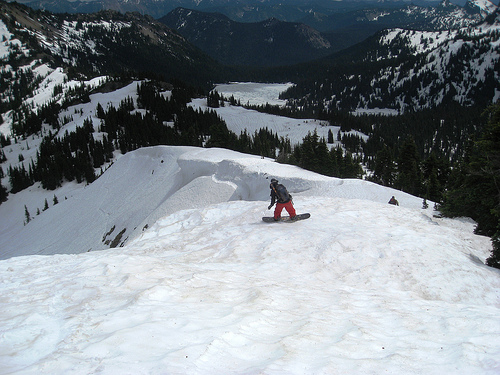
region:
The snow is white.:
[127, 258, 208, 359]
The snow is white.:
[127, 235, 302, 373]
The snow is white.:
[187, 275, 354, 373]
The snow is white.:
[155, 285, 263, 363]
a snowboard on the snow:
[255, 205, 310, 225]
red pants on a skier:
[270, 195, 295, 220]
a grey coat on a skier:
[265, 180, 290, 200]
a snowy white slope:
[0, 145, 495, 372]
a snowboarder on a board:
[251, 170, 307, 230]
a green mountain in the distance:
[165, 4, 330, 71]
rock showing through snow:
[101, 222, 125, 251]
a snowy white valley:
[217, 79, 286, 100]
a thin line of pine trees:
[17, 189, 69, 222]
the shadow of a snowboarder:
[249, 216, 266, 227]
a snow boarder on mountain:
[259, 176, 313, 223]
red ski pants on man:
[274, 201, 295, 218]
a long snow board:
[261, 211, 311, 223]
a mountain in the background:
[156, 7, 328, 75]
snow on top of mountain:
[187, 290, 325, 347]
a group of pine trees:
[288, 129, 365, 177]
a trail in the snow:
[204, 166, 258, 201]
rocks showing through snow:
[101, 226, 128, 249]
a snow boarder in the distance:
[388, 193, 400, 205]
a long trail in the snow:
[90, 168, 122, 222]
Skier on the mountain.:
[209, 101, 344, 261]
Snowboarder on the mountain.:
[253, 168, 390, 260]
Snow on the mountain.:
[126, 101, 400, 339]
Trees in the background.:
[123, 70, 412, 305]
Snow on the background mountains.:
[215, 17, 480, 134]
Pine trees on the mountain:
[39, 120, 110, 201]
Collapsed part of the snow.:
[148, 145, 358, 255]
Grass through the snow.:
[91, 220, 161, 256]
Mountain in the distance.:
[141, 5, 361, 80]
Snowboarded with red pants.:
[255, 174, 337, 231]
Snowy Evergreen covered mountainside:
[314, 16, 498, 268]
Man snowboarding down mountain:
[250, 171, 318, 230]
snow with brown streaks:
[88, 227, 423, 332]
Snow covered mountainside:
[81, 148, 463, 374]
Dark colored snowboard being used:
[251, 208, 318, 232]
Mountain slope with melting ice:
[37, 11, 194, 87]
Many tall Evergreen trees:
[32, 73, 216, 188]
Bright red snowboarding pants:
[256, 193, 338, 228]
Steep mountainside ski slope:
[156, 2, 360, 361]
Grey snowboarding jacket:
[261, 173, 300, 213]